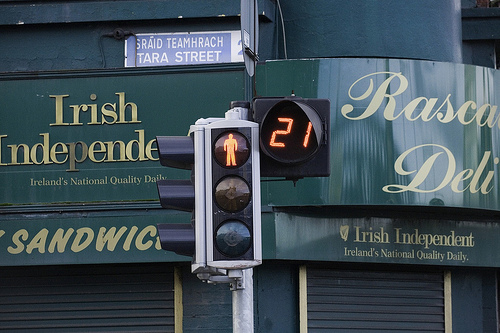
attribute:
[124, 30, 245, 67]
sign — blue, white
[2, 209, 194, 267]
sign — green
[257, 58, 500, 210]
sign — green, gold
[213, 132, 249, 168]
light — on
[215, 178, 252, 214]
light — off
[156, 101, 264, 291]
traffic light — lit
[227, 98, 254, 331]
pole — metal, silver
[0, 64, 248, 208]
sign — green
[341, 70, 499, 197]
lettering — cursive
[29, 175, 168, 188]
lettering — pring